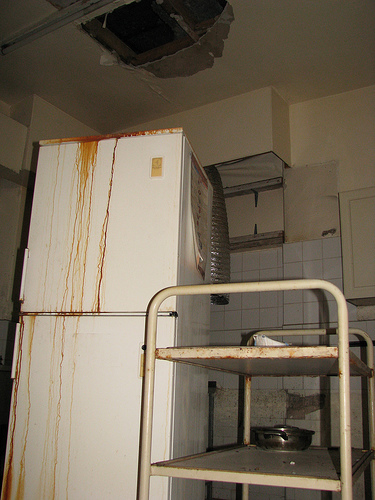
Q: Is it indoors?
A: Yes, it is indoors.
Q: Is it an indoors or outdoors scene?
A: It is indoors.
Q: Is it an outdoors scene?
A: No, it is indoors.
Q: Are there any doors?
A: Yes, there is a door.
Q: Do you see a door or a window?
A: Yes, there is a door.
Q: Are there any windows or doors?
A: Yes, there is a door.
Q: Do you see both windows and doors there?
A: No, there is a door but no windows.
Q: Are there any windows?
A: No, there are no windows.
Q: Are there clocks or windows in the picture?
A: No, there are no windows or clocks.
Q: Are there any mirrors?
A: No, there are no mirrors.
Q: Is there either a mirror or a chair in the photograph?
A: No, there are no mirrors or chairs.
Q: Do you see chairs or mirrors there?
A: No, there are no mirrors or chairs.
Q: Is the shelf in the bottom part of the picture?
A: Yes, the shelf is in the bottom of the image.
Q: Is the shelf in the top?
A: No, the shelf is in the bottom of the image.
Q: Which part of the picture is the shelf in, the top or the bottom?
A: The shelf is in the bottom of the image.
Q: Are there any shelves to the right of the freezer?
A: Yes, there is a shelf to the right of the freezer.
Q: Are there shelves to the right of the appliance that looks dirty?
A: Yes, there is a shelf to the right of the freezer.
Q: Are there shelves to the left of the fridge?
A: No, the shelf is to the right of the fridge.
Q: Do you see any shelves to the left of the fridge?
A: No, the shelf is to the right of the fridge.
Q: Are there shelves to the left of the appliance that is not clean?
A: No, the shelf is to the right of the fridge.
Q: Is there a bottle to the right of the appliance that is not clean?
A: No, there is a shelf to the right of the refrigerator.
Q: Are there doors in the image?
A: Yes, there is a door.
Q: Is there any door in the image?
A: Yes, there is a door.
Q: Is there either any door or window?
A: Yes, there is a door.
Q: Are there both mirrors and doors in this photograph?
A: No, there is a door but no mirrors.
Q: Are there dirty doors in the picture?
A: Yes, there is a dirty door.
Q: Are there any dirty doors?
A: Yes, there is a dirty door.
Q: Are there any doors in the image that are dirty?
A: Yes, there is a door that is dirty.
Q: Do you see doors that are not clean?
A: Yes, there is a dirty door.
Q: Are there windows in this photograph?
A: No, there are no windows.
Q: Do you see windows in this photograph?
A: No, there are no windows.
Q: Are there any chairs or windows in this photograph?
A: No, there are no windows or chairs.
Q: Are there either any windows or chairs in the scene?
A: No, there are no windows or chairs.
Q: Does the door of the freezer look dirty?
A: Yes, the door is dirty.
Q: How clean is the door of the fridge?
A: The door is dirty.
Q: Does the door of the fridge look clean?
A: No, the door is dirty.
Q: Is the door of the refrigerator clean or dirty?
A: The door is dirty.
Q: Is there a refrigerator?
A: Yes, there is a refrigerator.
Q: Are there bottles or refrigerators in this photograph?
A: Yes, there is a refrigerator.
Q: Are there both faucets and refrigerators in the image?
A: No, there is a refrigerator but no faucets.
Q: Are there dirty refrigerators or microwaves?
A: Yes, there is a dirty refrigerator.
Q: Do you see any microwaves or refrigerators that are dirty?
A: Yes, the refrigerator is dirty.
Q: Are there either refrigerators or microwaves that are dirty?
A: Yes, the refrigerator is dirty.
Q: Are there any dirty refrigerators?
A: Yes, there is a dirty refrigerator.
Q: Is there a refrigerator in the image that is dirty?
A: Yes, there is a refrigerator that is dirty.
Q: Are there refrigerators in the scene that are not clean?
A: Yes, there is a dirty refrigerator.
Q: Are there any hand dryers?
A: No, there are no hand dryers.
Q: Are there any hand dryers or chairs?
A: No, there are no hand dryers or chairs.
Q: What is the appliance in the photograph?
A: The appliance is a refrigerator.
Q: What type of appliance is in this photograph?
A: The appliance is a refrigerator.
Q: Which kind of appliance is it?
A: The appliance is a refrigerator.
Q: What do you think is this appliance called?
A: This is a refrigerator.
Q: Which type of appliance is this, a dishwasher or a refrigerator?
A: This is a refrigerator.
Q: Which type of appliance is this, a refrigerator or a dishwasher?
A: This is a refrigerator.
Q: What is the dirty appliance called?
A: The appliance is a refrigerator.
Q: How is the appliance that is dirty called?
A: The appliance is a refrigerator.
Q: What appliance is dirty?
A: The appliance is a refrigerator.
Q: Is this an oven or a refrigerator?
A: This is a refrigerator.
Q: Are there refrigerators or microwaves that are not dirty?
A: No, there is a refrigerator but it is dirty.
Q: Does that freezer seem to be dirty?
A: Yes, the freezer is dirty.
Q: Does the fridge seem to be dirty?
A: Yes, the fridge is dirty.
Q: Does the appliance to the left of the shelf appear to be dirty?
A: Yes, the fridge is dirty.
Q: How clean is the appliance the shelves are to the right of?
A: The fridge is dirty.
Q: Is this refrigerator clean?
A: No, the refrigerator is dirty.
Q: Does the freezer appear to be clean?
A: No, the freezer is dirty.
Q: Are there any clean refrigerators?
A: No, there is a refrigerator but it is dirty.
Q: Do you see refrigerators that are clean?
A: No, there is a refrigerator but it is dirty.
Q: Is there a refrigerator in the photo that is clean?
A: No, there is a refrigerator but it is dirty.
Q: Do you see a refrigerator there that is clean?
A: No, there is a refrigerator but it is dirty.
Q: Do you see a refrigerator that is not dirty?
A: No, there is a refrigerator but it is dirty.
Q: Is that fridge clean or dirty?
A: The fridge is dirty.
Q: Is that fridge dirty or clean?
A: The fridge is dirty.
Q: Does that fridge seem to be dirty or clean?
A: The fridge is dirty.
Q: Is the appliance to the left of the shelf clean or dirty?
A: The fridge is dirty.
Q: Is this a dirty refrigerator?
A: Yes, this is a dirty refrigerator.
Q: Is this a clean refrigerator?
A: No, this is a dirty refrigerator.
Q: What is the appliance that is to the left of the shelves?
A: The appliance is a refrigerator.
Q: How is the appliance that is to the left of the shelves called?
A: The appliance is a refrigerator.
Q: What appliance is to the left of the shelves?
A: The appliance is a refrigerator.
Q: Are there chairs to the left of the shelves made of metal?
A: No, there is a refrigerator to the left of the shelves.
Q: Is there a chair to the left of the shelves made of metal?
A: No, there is a refrigerator to the left of the shelves.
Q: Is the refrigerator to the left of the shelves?
A: Yes, the refrigerator is to the left of the shelves.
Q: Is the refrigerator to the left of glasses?
A: No, the refrigerator is to the left of the shelves.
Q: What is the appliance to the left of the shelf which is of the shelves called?
A: The appliance is a refrigerator.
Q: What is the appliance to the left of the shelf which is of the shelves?
A: The appliance is a refrigerator.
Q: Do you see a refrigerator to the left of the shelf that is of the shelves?
A: Yes, there is a refrigerator to the left of the shelf.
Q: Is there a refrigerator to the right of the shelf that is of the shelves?
A: No, the refrigerator is to the left of the shelf.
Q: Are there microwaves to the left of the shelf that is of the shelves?
A: No, there is a refrigerator to the left of the shelf.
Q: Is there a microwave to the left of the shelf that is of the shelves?
A: No, there is a refrigerator to the left of the shelf.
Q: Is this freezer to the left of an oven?
A: No, the freezer is to the left of a shelf.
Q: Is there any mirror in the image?
A: No, there are no mirrors.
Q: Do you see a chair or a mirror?
A: No, there are no mirrors or chairs.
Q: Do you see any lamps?
A: No, there are no lamps.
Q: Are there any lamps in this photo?
A: No, there are no lamps.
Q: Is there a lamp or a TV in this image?
A: No, there are no lamps or televisions.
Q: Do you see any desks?
A: No, there are no desks.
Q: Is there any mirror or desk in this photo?
A: No, there are no desks or mirrors.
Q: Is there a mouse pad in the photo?
A: No, there are no mouse pads.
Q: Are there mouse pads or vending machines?
A: No, there are no mouse pads or vending machines.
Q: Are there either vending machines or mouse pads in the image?
A: No, there are no mouse pads or vending machines.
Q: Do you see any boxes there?
A: No, there are no boxes.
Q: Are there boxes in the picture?
A: No, there are no boxes.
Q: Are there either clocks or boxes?
A: No, there are no boxes or clocks.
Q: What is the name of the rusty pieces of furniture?
A: The pieces of furniture are shelves.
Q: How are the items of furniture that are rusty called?
A: The pieces of furniture are shelves.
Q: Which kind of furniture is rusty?
A: The furniture is shelves.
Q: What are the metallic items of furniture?
A: The pieces of furniture are shelves.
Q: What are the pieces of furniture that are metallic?
A: The pieces of furniture are shelves.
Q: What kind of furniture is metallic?
A: The furniture is shelves.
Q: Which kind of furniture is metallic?
A: The furniture is shelves.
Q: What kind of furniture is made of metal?
A: The furniture is shelves.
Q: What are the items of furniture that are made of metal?
A: The pieces of furniture are shelves.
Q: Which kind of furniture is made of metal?
A: The furniture is shelves.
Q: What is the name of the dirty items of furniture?
A: The pieces of furniture are shelves.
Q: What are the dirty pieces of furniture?
A: The pieces of furniture are shelves.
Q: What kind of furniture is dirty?
A: The furniture is shelves.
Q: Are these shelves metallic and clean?
A: No, the shelves are metallic but dirty.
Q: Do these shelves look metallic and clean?
A: No, the shelves are metallic but dirty.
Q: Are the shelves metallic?
A: Yes, the shelves are metallic.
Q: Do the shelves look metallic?
A: Yes, the shelves are metallic.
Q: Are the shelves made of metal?
A: Yes, the shelves are made of metal.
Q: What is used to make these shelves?
A: The shelves are made of metal.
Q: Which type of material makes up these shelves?
A: The shelves are made of metal.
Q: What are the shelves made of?
A: The shelves are made of metal.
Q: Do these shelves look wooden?
A: No, the shelves are metallic.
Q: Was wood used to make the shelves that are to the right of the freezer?
A: No, the shelves are made of metal.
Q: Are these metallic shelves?
A: Yes, these are metallic shelves.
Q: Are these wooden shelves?
A: No, these are metallic shelves.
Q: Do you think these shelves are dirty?
A: Yes, the shelves are dirty.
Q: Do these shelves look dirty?
A: Yes, the shelves are dirty.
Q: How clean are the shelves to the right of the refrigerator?
A: The shelves are dirty.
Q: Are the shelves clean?
A: No, the shelves are dirty.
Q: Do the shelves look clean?
A: No, the shelves are dirty.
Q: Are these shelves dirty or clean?
A: The shelves are dirty.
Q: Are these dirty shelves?
A: Yes, these are dirty shelves.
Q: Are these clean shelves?
A: No, these are dirty shelves.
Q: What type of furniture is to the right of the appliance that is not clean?
A: The pieces of furniture are shelves.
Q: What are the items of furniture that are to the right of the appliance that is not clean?
A: The pieces of furniture are shelves.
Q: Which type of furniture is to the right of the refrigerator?
A: The pieces of furniture are shelves.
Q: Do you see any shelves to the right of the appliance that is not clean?
A: Yes, there are shelves to the right of the fridge.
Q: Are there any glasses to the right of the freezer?
A: No, there are shelves to the right of the freezer.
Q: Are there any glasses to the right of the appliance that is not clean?
A: No, there are shelves to the right of the freezer.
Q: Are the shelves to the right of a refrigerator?
A: Yes, the shelves are to the right of a refrigerator.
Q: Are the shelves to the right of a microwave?
A: No, the shelves are to the right of a refrigerator.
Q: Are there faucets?
A: No, there are no faucets.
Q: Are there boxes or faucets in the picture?
A: No, there are no faucets or boxes.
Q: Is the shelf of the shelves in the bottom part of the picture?
A: Yes, the shelf is in the bottom of the image.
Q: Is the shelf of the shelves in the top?
A: No, the shelf is in the bottom of the image.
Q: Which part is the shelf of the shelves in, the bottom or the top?
A: The shelf is in the bottom of the image.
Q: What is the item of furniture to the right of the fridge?
A: The piece of furniture is a shelf.